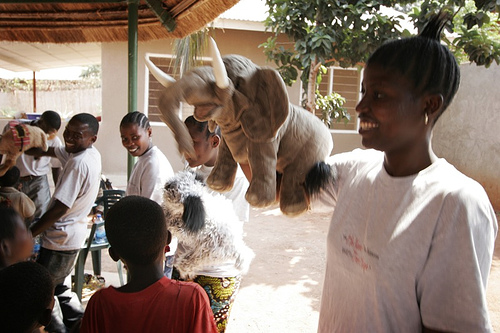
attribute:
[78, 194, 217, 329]
child — african american, young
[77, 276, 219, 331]
shirt — red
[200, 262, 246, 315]
lesso — blue, yellow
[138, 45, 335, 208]
elephant — grey, stuffed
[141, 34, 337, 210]
elephant puppet — gray , stuffed 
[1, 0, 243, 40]
awning — brown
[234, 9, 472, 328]
person — happy, african american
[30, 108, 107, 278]
male — african american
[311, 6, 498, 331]
woman — african american, smiling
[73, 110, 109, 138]
hair — short, black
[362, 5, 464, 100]
hair — black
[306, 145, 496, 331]
shirt — red, white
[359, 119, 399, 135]
teeth — white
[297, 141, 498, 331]
t shirt — white , grey 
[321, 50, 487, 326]
child — small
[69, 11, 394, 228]
elephant — stuffed , gray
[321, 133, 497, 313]
shirt — grey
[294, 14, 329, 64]
leaves — green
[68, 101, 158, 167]
people — smiling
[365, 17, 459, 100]
hair — black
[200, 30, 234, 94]
tusk — white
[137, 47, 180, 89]
tusk — white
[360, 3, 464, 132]
hair — black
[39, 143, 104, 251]
shirt — gray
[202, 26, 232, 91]
tusk — white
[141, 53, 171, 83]
tusk — white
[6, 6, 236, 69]
umbrella — grass